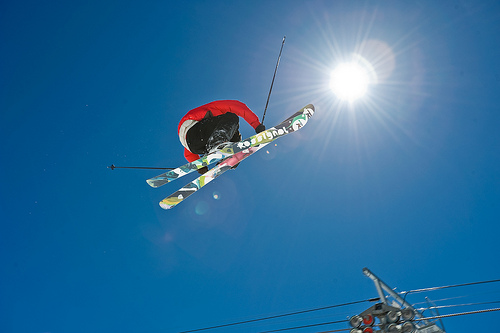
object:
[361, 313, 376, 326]
wheels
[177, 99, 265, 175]
man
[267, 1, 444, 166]
sun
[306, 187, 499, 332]
sky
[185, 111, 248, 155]
pants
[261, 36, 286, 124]
ski pole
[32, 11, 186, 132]
sky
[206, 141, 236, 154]
shoe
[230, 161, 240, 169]
shoe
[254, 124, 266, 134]
glove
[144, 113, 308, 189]
ski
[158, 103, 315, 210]
ski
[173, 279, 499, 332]
wire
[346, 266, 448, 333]
ski lift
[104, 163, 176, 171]
ski pole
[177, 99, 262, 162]
coat